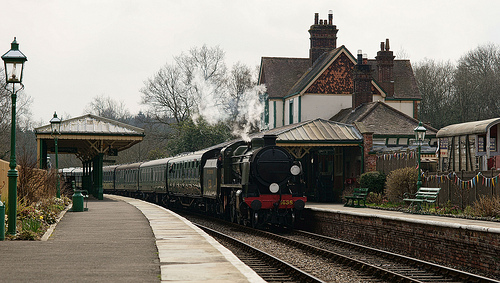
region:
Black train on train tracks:
[102, 135, 317, 231]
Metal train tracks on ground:
[235, 228, 498, 281]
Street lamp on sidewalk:
[0, 33, 29, 239]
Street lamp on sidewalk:
[47, 109, 64, 196]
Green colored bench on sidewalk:
[341, 183, 372, 208]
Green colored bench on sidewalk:
[398, 183, 443, 213]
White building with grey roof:
[247, 4, 431, 130]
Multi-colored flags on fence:
[420, 165, 498, 196]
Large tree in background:
[137, 37, 254, 140]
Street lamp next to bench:
[411, 119, 425, 187]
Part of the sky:
[53, 27, 100, 77]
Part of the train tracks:
[258, 251, 281, 268]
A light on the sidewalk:
[1, 35, 31, 242]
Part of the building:
[305, 101, 330, 113]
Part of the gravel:
[286, 248, 299, 260]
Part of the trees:
[463, 75, 478, 104]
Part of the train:
[173, 169, 210, 185]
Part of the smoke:
[246, 94, 258, 114]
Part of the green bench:
[351, 187, 365, 195]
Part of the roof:
[273, 64, 292, 79]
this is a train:
[50, 120, 350, 250]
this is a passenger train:
[20, 91, 317, 247]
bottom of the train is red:
[236, 187, 319, 227]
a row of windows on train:
[93, 162, 223, 189]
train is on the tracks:
[63, 114, 480, 272]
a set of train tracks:
[250, 225, 450, 279]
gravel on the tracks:
[248, 228, 392, 280]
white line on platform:
[156, 196, 256, 281]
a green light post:
[3, 32, 48, 233]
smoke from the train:
[228, 67, 274, 147]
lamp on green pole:
[2, 36, 28, 90]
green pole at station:
[1, 94, 28, 237]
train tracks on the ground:
[215, 221, 496, 281]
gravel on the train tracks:
[234, 222, 388, 274]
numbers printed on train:
[276, 196, 296, 207]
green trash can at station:
[67, 182, 95, 210]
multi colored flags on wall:
[411, 160, 498, 198]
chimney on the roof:
[353, 46, 378, 108]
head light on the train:
[262, 180, 282, 195]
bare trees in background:
[145, 68, 201, 128]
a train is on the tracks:
[98, 131, 378, 229]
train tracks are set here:
[251, 230, 483, 282]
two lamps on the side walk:
[0, 30, 65, 245]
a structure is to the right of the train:
[253, 10, 447, 193]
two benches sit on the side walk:
[335, 159, 445, 222]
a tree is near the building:
[133, 31, 256, 144]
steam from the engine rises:
[193, 47, 260, 149]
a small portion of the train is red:
[236, 186, 310, 212]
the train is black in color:
[109, 133, 311, 225]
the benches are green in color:
[343, 170, 447, 223]